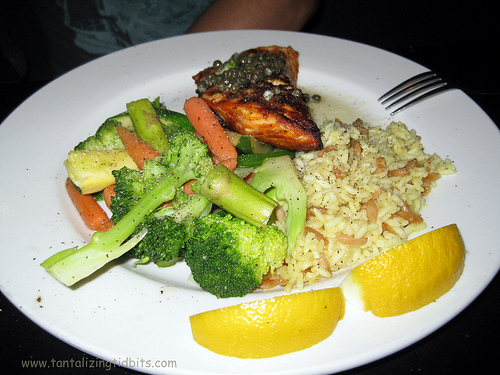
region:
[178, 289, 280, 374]
YEllow fruit on a plate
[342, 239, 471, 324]
YEllow fruit on a plate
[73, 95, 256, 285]
Green and orange veggies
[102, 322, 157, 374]
White edge of a plate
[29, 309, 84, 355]
White edge of a plate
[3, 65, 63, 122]
White edge of a plate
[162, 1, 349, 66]
White edge of a plate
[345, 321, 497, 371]
White edge of a plate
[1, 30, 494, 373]
plate filled with lots of food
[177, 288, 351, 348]
lemon wedge on side of plate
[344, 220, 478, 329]
lemon slice on side of plate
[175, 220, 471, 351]
cut up lemon on plate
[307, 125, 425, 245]
pile of rice on a plate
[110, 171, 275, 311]
broccoli on a plate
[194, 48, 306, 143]
piece of fish on a plate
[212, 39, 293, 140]
orange and black fish on plate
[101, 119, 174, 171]
carrot pieces on plate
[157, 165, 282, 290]
heads and stems of broccoli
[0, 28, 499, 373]
A white ceramic plate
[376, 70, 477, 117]
A silver fork on a plate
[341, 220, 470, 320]
A wedge of lemon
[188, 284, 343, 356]
A wedge of lemon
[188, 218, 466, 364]
A pair of lemon wedges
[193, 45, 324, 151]
some chicken on a plate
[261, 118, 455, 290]
some rice on a plate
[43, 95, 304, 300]
some broccoli on a plate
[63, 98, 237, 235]
some carrots on a plate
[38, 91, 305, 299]
some vegetables on a plate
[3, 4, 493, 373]
a white plate is being served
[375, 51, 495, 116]
a fork is upside down on the plate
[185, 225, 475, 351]
quartered lemon slices are on the dish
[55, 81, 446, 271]
the food has been salted and peppered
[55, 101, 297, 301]
a vegetable medley is on the dish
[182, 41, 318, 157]
capers are on a piece of salmon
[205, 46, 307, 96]
the capers are round and black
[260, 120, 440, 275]
a rice mixture is on the plate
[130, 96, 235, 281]
baby carrots are next to the broccoli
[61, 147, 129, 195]
squash is next to the carrots and broccoli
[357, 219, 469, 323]
lemon wedge on the plate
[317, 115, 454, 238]
brown and yellow rice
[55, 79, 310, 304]
green chopped broccoli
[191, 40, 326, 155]
salmon and capers with sauce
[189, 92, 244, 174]
piece of baby carrot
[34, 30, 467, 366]
complete meal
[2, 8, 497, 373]
circular white ceramic plate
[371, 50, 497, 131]
silver metal fork on the plate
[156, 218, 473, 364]
two pieces of lemon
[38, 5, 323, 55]
person wearing a blue shirt